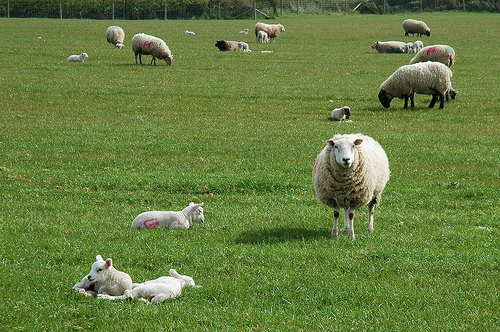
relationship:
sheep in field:
[312, 130, 392, 245] [2, 15, 499, 330]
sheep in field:
[378, 62, 457, 113] [2, 15, 499, 330]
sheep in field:
[407, 45, 456, 66] [2, 15, 499, 330]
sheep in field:
[401, 18, 432, 39] [2, 15, 499, 330]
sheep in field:
[131, 32, 173, 66] [2, 15, 499, 330]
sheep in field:
[105, 25, 127, 51] [2, 15, 499, 330]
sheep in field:
[256, 21, 287, 43] [2, 15, 499, 330]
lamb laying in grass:
[131, 268, 198, 308] [2, 15, 499, 330]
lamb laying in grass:
[69, 255, 132, 301] [2, 15, 499, 330]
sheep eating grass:
[131, 32, 173, 66] [2, 15, 499, 330]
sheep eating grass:
[401, 18, 432, 39] [426, 34, 440, 41]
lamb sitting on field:
[329, 105, 353, 122] [2, 15, 499, 330]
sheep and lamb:
[256, 21, 287, 43] [256, 29, 271, 45]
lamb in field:
[256, 29, 271, 45] [2, 15, 499, 330]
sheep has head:
[312, 130, 392, 245] [325, 137, 363, 169]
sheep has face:
[378, 62, 457, 113] [378, 89, 393, 109]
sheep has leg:
[378, 62, 457, 113] [403, 96, 410, 110]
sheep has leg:
[378, 62, 457, 113] [409, 92, 415, 108]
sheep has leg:
[378, 62, 457, 113] [427, 92, 437, 109]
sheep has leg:
[378, 62, 457, 113] [437, 92, 447, 110]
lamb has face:
[329, 105, 353, 122] [342, 107, 351, 119]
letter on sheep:
[425, 45, 436, 56] [407, 45, 456, 66]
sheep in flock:
[312, 130, 392, 245] [64, 18, 458, 307]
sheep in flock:
[131, 32, 173, 66] [64, 18, 458, 307]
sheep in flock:
[105, 25, 127, 51] [64, 18, 458, 307]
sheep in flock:
[256, 21, 287, 43] [64, 18, 458, 307]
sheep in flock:
[401, 18, 432, 39] [64, 18, 458, 307]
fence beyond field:
[2, 1, 497, 20] [2, 15, 499, 330]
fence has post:
[2, 1, 497, 20] [162, 2, 170, 20]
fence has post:
[2, 1, 497, 20] [251, 1, 259, 22]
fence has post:
[2, 1, 497, 20] [57, 2, 65, 21]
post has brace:
[251, 1, 259, 22] [256, 6, 269, 19]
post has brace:
[251, 1, 259, 22] [236, 8, 253, 20]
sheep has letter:
[131, 32, 173, 66] [142, 39, 153, 49]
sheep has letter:
[407, 45, 456, 66] [425, 45, 436, 56]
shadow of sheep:
[232, 225, 332, 246] [312, 130, 392, 245]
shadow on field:
[232, 225, 332, 246] [2, 15, 499, 330]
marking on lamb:
[144, 217, 160, 229] [130, 201, 209, 233]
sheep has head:
[378, 62, 457, 113] [375, 86, 391, 109]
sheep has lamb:
[370, 38, 405, 54] [405, 42, 413, 54]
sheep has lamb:
[370, 38, 405, 54] [411, 41, 425, 53]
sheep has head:
[105, 25, 127, 51] [114, 43, 126, 50]